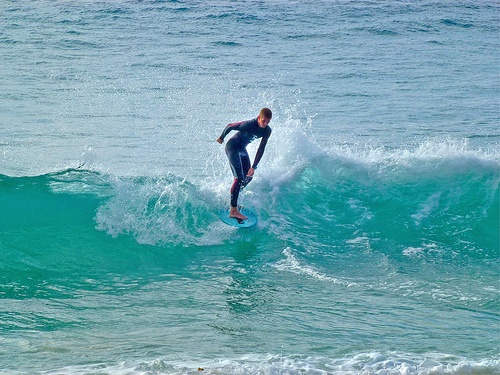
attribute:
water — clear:
[0, 0, 499, 374]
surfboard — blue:
[206, 187, 316, 238]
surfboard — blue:
[217, 189, 262, 231]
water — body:
[233, 209, 434, 329]